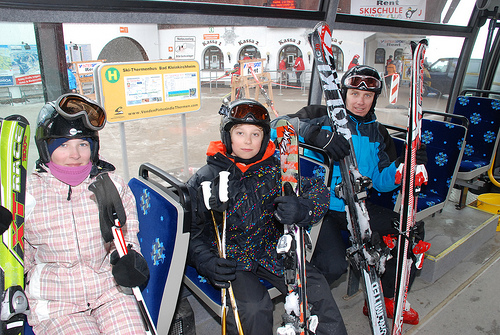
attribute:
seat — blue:
[118, 159, 195, 333]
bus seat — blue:
[141, 190, 411, 221]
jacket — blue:
[265, 94, 425, 210]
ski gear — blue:
[277, 100, 409, 295]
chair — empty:
[374, 87, 495, 204]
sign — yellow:
[86, 53, 213, 119]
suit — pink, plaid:
[10, 154, 170, 333]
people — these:
[44, 67, 456, 284]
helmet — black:
[213, 96, 274, 163]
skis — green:
[0, 112, 28, 334]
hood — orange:
[204, 136, 274, 171]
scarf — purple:
[45, 160, 92, 183]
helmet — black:
[35, 98, 99, 168]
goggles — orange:
[51, 90, 104, 128]